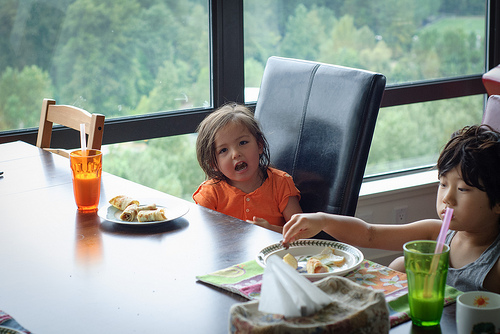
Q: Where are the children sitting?
A: In a chair at the table?.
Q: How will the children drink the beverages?
A: Through a straw.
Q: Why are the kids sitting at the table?
A: To eat a meal.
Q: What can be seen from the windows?
A: Trees.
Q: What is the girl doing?
A: Looking at the camera.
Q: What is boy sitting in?
A: Chair.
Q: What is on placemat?
A: Plate.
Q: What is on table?
A: Tissue box.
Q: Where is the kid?
A: On the chair.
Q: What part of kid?
A: Head.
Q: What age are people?
A: Children.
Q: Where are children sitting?
A: Table.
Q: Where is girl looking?
A: Camera.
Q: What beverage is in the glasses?
A: Milk.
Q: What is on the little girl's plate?
A: Egg rolls.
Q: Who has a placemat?
A: Child on right.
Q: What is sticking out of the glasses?
A: Straws.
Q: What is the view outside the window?
A: Trees.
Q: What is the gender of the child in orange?
A: Female.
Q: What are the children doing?
A: Eating a meal.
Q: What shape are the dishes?
A: Round.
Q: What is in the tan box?
A: Tissues.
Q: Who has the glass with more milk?
A: Child on left.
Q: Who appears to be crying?
A: The girl on the left.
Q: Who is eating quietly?
A: The child on the right.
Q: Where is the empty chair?
A: By the window.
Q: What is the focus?
A: Kids eating.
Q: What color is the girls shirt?
A: Orange.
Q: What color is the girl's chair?
A: Black.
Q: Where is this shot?
A: Dining room.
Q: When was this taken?
A: Daytime.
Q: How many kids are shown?
A: 2.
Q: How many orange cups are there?
A: 1.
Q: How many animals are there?
A: 0.